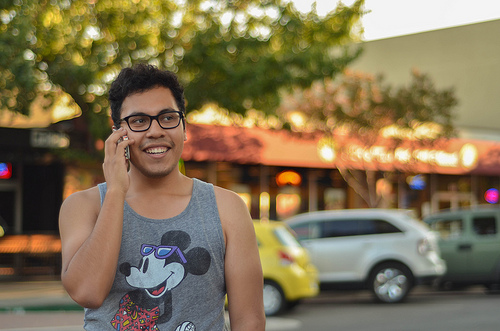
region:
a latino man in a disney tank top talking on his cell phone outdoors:
[40, 55, 292, 329]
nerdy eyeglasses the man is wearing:
[120, 106, 183, 136]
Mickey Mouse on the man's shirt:
[113, 219, 212, 320]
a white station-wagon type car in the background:
[282, 196, 447, 297]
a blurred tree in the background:
[10, 8, 367, 70]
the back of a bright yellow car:
[241, 208, 318, 314]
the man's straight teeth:
[142, 142, 173, 157]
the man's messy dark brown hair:
[110, 66, 185, 101]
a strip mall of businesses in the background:
[204, 111, 498, 219]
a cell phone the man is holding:
[113, 133, 128, 158]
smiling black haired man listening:
[53, 66, 276, 330]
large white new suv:
[277, 206, 443, 301]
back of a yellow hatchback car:
[252, 217, 317, 307]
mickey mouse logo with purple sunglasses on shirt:
[110, 229, 208, 328]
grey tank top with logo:
[87, 180, 229, 330]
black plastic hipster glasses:
[115, 111, 187, 130]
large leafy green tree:
[0, 2, 370, 202]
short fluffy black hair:
[106, 64, 185, 121]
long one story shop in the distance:
[41, 111, 498, 292]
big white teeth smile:
[143, 142, 172, 159]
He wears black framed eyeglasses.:
[107, 64, 191, 138]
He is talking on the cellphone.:
[94, 113, 137, 168]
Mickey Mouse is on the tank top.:
[96, 178, 219, 329]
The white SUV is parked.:
[289, 206, 446, 296]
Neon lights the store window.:
[259, 166, 314, 220]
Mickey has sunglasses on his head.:
[123, 228, 211, 297]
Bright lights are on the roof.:
[314, 138, 479, 181]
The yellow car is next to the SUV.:
[249, 218, 325, 315]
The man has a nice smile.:
[122, 101, 189, 191]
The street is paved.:
[314, 293, 490, 323]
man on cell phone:
[53, 58, 272, 330]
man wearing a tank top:
[54, 64, 268, 329]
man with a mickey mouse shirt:
[58, 55, 272, 330]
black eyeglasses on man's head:
[122, 108, 184, 131]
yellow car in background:
[247, 213, 321, 317]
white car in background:
[285, 209, 447, 303]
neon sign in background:
[269, 168, 306, 188]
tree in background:
[280, 74, 464, 207]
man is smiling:
[137, 138, 177, 163]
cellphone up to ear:
[108, 124, 135, 166]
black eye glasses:
[117, 105, 188, 134]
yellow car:
[219, 208, 325, 318]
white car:
[271, 202, 446, 311]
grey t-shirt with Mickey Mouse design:
[79, 171, 227, 327]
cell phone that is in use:
[105, 120, 140, 175]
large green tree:
[1, 0, 368, 159]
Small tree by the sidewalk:
[294, 59, 467, 253]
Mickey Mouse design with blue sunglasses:
[110, 226, 208, 330]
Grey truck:
[414, 204, 499, 293]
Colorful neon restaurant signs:
[269, 165, 499, 208]